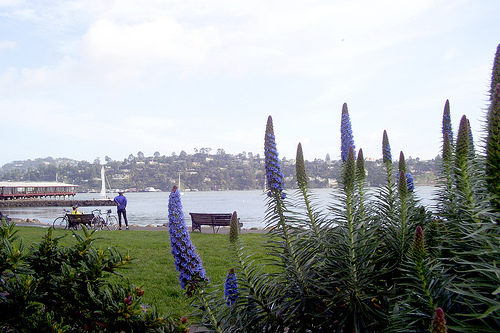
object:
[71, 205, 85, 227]
person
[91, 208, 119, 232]
bicycle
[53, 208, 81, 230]
bicycle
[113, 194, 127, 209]
shirt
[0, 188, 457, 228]
water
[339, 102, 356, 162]
purple flower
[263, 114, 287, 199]
purple flower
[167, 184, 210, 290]
purple flower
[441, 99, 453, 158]
purple flower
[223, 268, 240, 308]
purple flower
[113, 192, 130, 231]
man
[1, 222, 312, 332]
grass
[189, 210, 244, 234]
bench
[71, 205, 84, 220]
bench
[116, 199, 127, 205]
purple